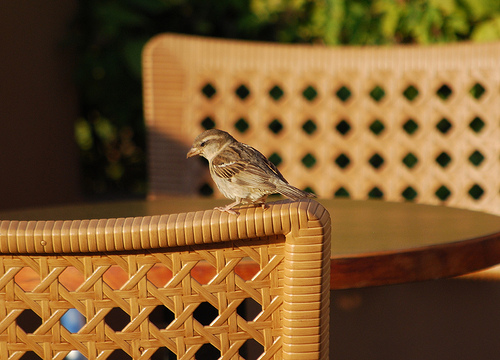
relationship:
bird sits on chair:
[182, 116, 312, 221] [2, 198, 336, 353]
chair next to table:
[2, 198, 336, 353] [5, 190, 499, 295]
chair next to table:
[131, 27, 497, 209] [5, 190, 499, 295]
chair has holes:
[2, 198, 336, 353] [14, 259, 270, 358]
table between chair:
[5, 190, 499, 295] [139, 29, 500, 279]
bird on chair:
[182, 116, 312, 221] [2, 198, 336, 353]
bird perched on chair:
[182, 116, 312, 221] [2, 198, 336, 353]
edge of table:
[331, 232, 496, 289] [5, 190, 499, 295]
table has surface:
[5, 190, 499, 295] [8, 187, 496, 255]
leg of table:
[332, 285, 378, 359] [5, 190, 499, 295]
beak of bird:
[184, 145, 201, 163] [182, 116, 312, 221]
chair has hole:
[2, 198, 336, 353] [228, 252, 265, 285]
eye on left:
[195, 138, 208, 151] [193, 133, 223, 159]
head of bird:
[177, 124, 237, 164] [182, 116, 312, 221]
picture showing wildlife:
[7, 5, 499, 360] [182, 116, 312, 221]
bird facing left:
[182, 116, 312, 221] [7, 9, 102, 352]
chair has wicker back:
[2, 198, 336, 353] [14, 259, 270, 358]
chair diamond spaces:
[2, 198, 336, 353] [99, 258, 134, 294]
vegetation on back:
[80, 5, 499, 44] [13, 7, 499, 34]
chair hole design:
[2, 198, 336, 353] [140, 263, 177, 292]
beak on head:
[184, 145, 201, 163] [177, 124, 237, 164]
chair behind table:
[131, 27, 497, 209] [5, 190, 499, 295]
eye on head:
[195, 138, 208, 151] [177, 124, 237, 164]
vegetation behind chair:
[80, 5, 499, 44] [131, 27, 497, 209]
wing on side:
[215, 161, 247, 180] [210, 147, 263, 201]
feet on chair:
[209, 198, 272, 222] [2, 198, 336, 353]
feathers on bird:
[213, 145, 307, 202] [182, 116, 312, 221]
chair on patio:
[139, 29, 500, 279] [11, 36, 499, 354]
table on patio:
[5, 190, 499, 295] [11, 36, 499, 354]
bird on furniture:
[182, 116, 312, 221] [11, 36, 499, 354]